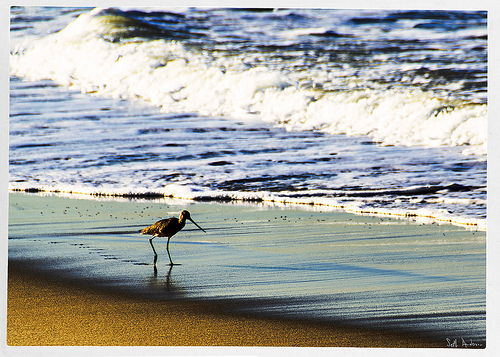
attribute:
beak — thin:
[185, 214, 207, 234]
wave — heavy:
[11, 5, 485, 153]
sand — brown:
[48, 268, 355, 340]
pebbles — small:
[41, 179, 364, 226]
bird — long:
[137, 186, 218, 287]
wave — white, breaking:
[61, 51, 459, 167]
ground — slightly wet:
[202, 193, 467, 349]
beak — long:
[184, 214, 206, 231]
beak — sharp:
[183, 211, 209, 234]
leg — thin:
[145, 232, 161, 263]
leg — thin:
[162, 235, 182, 269]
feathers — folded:
[146, 215, 175, 234]